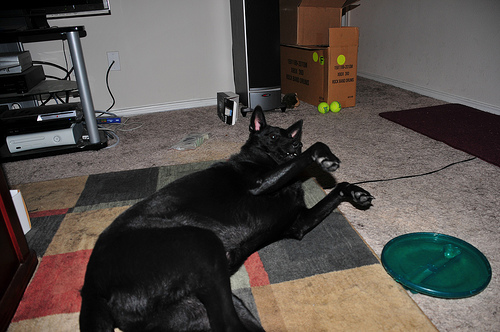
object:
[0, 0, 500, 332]
room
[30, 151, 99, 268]
train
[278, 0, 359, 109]
boxes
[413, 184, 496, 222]
carpeting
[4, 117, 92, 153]
game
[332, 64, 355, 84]
text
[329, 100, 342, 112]
ball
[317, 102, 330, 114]
ball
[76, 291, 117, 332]
dog's tail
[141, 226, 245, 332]
back leg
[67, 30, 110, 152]
television stand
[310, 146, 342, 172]
paw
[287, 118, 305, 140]
ear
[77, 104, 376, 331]
dog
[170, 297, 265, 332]
leg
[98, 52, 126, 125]
wall wire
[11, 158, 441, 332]
mat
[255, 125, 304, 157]
face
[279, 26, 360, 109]
cardboard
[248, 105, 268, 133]
ear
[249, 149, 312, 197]
leg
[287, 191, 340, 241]
leg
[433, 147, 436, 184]
bad picture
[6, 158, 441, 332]
rug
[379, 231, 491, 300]
frisbee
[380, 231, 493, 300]
plate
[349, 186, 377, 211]
paw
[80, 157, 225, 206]
remote control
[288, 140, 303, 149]
nose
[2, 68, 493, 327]
ground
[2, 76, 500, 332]
floor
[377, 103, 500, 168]
rug